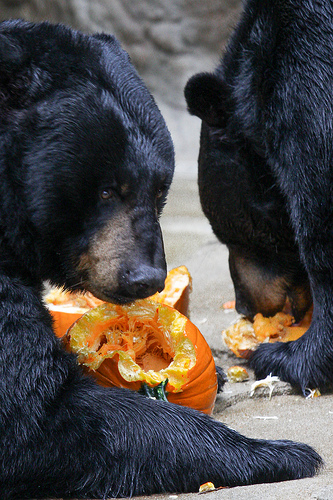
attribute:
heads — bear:
[8, 32, 308, 319]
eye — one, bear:
[98, 182, 113, 200]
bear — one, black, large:
[182, 32, 332, 392]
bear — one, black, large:
[2, 29, 177, 482]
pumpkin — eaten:
[68, 300, 216, 414]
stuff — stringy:
[103, 318, 160, 351]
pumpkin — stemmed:
[109, 297, 240, 415]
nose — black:
[111, 244, 180, 295]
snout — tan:
[81, 220, 189, 293]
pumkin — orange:
[73, 312, 223, 424]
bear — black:
[26, 46, 205, 337]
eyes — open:
[90, 172, 171, 201]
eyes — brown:
[95, 169, 189, 207]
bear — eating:
[192, 118, 331, 329]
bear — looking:
[28, 56, 167, 303]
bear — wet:
[1, 36, 229, 384]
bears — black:
[17, 49, 323, 339]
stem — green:
[127, 375, 196, 408]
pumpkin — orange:
[77, 303, 254, 437]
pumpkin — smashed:
[76, 297, 207, 372]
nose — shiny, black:
[131, 247, 212, 293]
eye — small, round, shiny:
[91, 183, 159, 216]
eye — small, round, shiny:
[138, 173, 173, 216]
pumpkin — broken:
[66, 275, 251, 411]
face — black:
[31, 98, 224, 292]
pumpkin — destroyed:
[41, 264, 320, 492]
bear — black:
[1, 18, 324, 496]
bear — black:
[184, 0, 331, 396]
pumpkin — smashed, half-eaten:
[41, 264, 217, 415]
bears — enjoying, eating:
[24, 32, 330, 384]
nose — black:
[127, 254, 203, 316]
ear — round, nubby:
[166, 64, 238, 121]